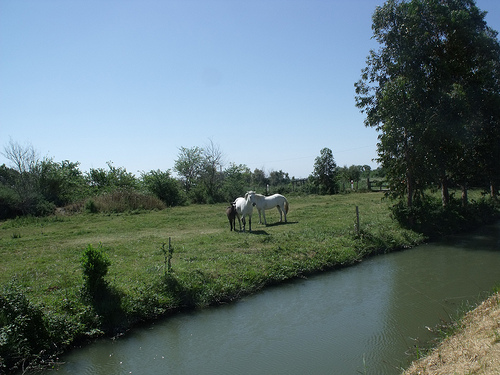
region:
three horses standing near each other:
[226, 190, 290, 229]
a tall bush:
[81, 243, 128, 324]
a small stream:
[51, 232, 498, 372]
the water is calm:
[56, 244, 498, 372]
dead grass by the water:
[404, 297, 498, 374]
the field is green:
[1, 165, 411, 357]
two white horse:
[233, 191, 285, 228]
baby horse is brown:
[227, 203, 236, 228]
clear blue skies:
[4, 3, 381, 164]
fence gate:
[366, 178, 391, 193]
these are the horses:
[216, 187, 291, 224]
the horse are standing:
[220, 180, 290, 235]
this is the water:
[293, 290, 387, 362]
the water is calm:
[263, 291, 374, 373]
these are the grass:
[178, 232, 240, 285]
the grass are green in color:
[162, 223, 231, 281]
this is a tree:
[363, 16, 480, 198]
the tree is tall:
[366, 7, 476, 191]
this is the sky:
[110, 9, 252, 101]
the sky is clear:
[140, 4, 252, 99]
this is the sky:
[118, 30, 178, 66]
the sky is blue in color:
[129, 18, 226, 75]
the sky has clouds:
[122, 82, 184, 165]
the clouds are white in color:
[107, 129, 169, 181]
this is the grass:
[107, 241, 164, 293]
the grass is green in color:
[115, 237, 152, 279]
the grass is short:
[115, 258, 138, 282]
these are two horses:
[209, 189, 299, 231]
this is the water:
[281, 302, 354, 358]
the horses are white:
[233, 185, 297, 227]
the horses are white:
[217, 178, 306, 239]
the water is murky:
[236, 279, 362, 370]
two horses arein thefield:
[215, 182, 306, 249]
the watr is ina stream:
[218, 310, 401, 374]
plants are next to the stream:
[136, 244, 271, 298]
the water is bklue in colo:
[226, 302, 323, 373]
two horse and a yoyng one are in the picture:
[223, 180, 278, 230]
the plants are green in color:
[118, 239, 215, 301]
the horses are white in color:
[243, 188, 301, 231]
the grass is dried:
[463, 310, 494, 374]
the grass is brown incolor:
[469, 318, 483, 373]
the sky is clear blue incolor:
[243, 151, 304, 169]